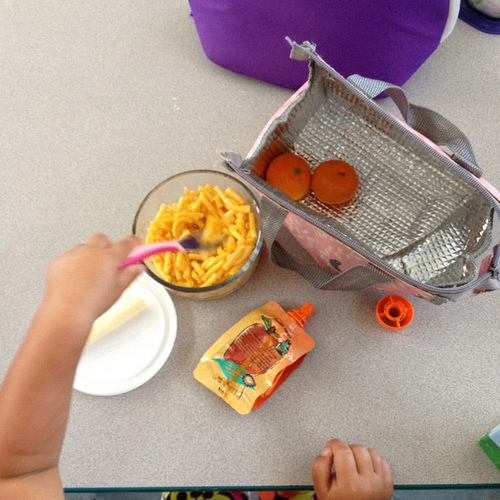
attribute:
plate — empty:
[124, 306, 162, 365]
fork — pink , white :
[119, 220, 219, 286]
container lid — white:
[50, 265, 182, 396]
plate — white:
[65, 265, 179, 401]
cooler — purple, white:
[188, 1, 460, 97]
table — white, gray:
[2, 2, 498, 487]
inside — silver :
[220, 43, 492, 287]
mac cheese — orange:
[140, 182, 258, 289]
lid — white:
[72, 272, 177, 394]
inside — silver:
[245, 67, 490, 287]